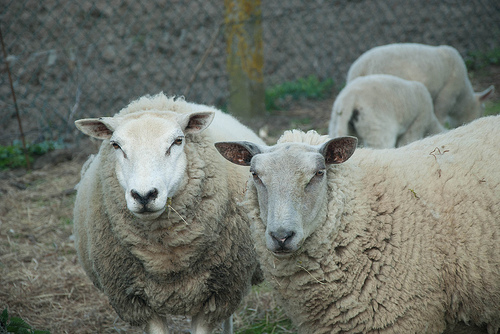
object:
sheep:
[210, 114, 500, 334]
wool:
[110, 165, 228, 310]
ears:
[73, 116, 116, 141]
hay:
[0, 163, 136, 334]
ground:
[0, 0, 500, 334]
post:
[226, 5, 265, 115]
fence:
[0, 0, 500, 143]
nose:
[269, 230, 295, 244]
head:
[68, 105, 214, 222]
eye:
[110, 139, 135, 160]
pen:
[0, 0, 500, 331]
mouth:
[133, 207, 160, 215]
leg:
[127, 309, 175, 333]